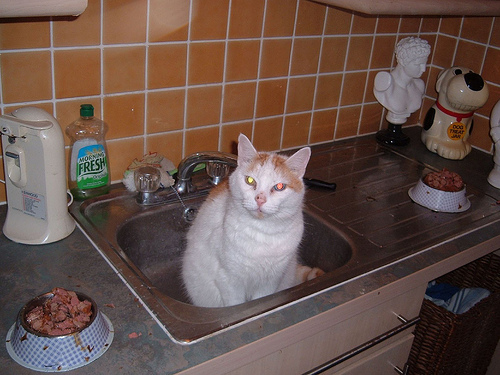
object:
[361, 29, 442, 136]
statue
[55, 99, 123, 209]
soap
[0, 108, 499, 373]
counter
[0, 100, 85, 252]
opener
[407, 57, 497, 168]
jar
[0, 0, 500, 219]
wall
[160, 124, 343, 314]
cat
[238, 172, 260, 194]
eye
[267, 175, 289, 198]
eye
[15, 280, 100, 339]
food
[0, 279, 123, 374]
bowl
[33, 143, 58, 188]
white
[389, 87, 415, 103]
white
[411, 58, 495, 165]
dog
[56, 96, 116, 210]
meadow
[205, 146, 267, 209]
spots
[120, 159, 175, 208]
knob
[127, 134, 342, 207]
faucet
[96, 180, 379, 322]
sink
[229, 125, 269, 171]
ears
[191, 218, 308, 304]
fur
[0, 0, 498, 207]
backsplash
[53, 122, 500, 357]
stainless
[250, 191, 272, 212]
nose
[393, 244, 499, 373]
basket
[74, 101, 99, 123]
cap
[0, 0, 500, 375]
kitchen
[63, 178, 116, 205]
liquid